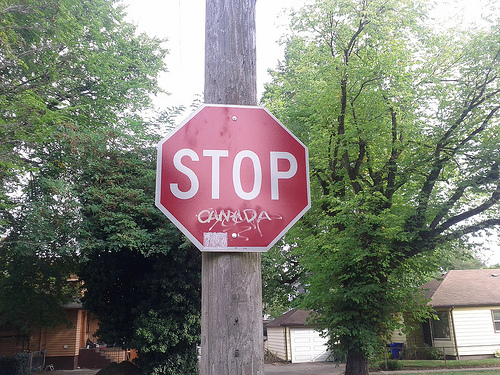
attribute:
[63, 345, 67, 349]
vent — white 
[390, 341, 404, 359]
trash can — blue 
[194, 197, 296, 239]
words — white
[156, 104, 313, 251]
sign — like octagon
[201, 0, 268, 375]
pole — tall, gray, wooden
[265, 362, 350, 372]
driveway — concrete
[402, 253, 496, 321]
house's roof — brown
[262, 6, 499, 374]
tree — green 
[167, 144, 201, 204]
letter s — white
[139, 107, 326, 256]
sign — red 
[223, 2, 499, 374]
branches — green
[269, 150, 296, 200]
letter p — white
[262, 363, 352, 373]
drive way — paved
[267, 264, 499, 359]
house — tan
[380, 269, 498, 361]
house — tan